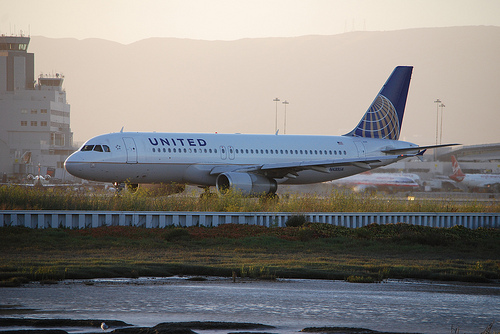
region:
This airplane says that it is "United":
[146, 128, 208, 153]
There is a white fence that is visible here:
[382, 208, 399, 245]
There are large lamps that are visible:
[430, 96, 447, 133]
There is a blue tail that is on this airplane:
[381, 59, 411, 136]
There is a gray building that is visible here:
[10, 53, 39, 140]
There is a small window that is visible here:
[84, 133, 96, 170]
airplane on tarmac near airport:
[58, 59, 470, 209]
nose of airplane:
[58, 126, 144, 186]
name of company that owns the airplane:
[142, 134, 214, 152]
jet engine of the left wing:
[209, 167, 290, 202]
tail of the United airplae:
[348, 62, 418, 143]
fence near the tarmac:
[3, 204, 498, 237]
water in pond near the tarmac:
[9, 259, 496, 330]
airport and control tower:
[3, 29, 68, 182]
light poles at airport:
[430, 94, 453, 144]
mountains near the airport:
[73, 22, 493, 94]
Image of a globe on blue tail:
[342, 65, 416, 141]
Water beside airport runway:
[4, 273, 496, 333]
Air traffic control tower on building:
[0, 31, 77, 181]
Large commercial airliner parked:
[63, 64, 463, 201]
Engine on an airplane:
[216, 171, 279, 197]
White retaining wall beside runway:
[1, 208, 497, 228]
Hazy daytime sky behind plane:
[0, 0, 499, 148]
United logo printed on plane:
[148, 134, 205, 147]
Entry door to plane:
[122, 133, 140, 167]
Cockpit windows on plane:
[80, 144, 112, 151]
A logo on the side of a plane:
[148, 135, 209, 148]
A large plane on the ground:
[62, 62, 421, 198]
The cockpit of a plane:
[65, 132, 122, 180]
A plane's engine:
[213, 168, 280, 199]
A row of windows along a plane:
[149, 144, 352, 158]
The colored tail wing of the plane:
[357, 61, 413, 143]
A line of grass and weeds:
[2, 182, 498, 212]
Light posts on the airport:
[270, 95, 293, 136]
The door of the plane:
[120, 135, 138, 165]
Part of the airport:
[0, 30, 92, 181]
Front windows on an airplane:
[78, 142, 111, 157]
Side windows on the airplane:
[150, 143, 356, 159]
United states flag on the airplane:
[334, 135, 344, 149]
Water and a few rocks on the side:
[2, 275, 499, 332]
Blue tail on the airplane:
[346, 61, 412, 139]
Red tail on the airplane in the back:
[447, 152, 464, 186]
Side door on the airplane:
[122, 135, 139, 165]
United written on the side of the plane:
[142, 134, 211, 147]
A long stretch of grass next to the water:
[2, 224, 499, 281]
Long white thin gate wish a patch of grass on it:
[0, 210, 497, 226]